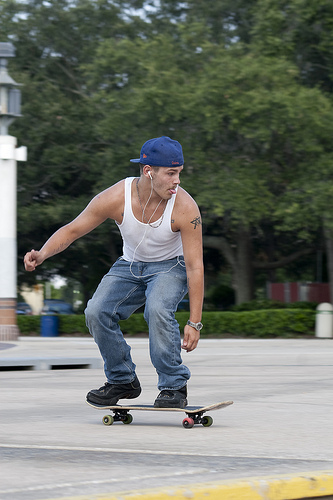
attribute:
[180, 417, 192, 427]
wheel — red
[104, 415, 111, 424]
wheel — yellow, white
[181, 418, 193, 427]
wheel — yellow, white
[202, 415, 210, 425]
wheel — yellow, white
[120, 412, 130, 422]
wheel — yellow, white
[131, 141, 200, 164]
cap — blue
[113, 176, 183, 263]
shirt — white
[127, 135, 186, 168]
hat — blue